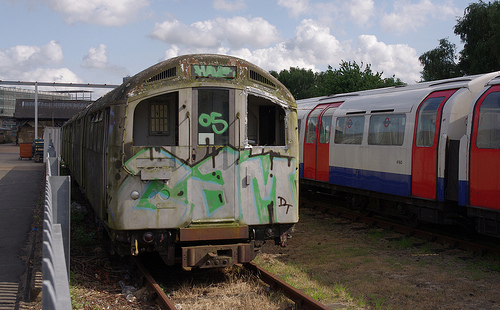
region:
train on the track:
[78, 48, 300, 274]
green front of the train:
[186, 99, 236, 144]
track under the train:
[153, 265, 294, 309]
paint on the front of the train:
[108, 64, 293, 242]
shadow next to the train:
[78, 258, 140, 308]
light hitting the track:
[223, 280, 273, 308]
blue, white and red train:
[343, 93, 475, 203]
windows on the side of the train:
[319, 103, 421, 159]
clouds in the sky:
[31, 11, 150, 71]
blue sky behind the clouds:
[6, 8, 32, 31]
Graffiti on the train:
[134, 150, 298, 216]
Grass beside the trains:
[298, 211, 498, 305]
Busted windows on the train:
[133, 97, 285, 144]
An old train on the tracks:
[61, 60, 294, 266]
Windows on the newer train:
[335, 108, 404, 146]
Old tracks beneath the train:
[145, 265, 325, 303]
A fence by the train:
[36, 137, 63, 308]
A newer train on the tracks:
[301, 72, 496, 227]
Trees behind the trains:
[285, 3, 492, 95]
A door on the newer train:
[308, 104, 330, 179]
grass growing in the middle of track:
[196, 275, 265, 297]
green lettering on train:
[193, 104, 237, 129]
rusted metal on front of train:
[173, 238, 267, 276]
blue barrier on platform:
[21, 191, 73, 297]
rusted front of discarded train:
[103, 49, 307, 244]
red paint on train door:
[416, 155, 431, 182]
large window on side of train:
[331, 108, 413, 150]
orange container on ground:
[7, 133, 41, 161]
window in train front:
[141, 98, 169, 138]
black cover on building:
[8, 90, 91, 120]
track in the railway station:
[122, 267, 303, 308]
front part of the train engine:
[116, 54, 311, 278]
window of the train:
[333, 109, 403, 150]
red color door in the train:
[407, 87, 476, 202]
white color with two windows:
[341, 93, 416, 198]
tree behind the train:
[288, 60, 415, 92]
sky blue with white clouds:
[157, 8, 419, 42]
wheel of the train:
[396, 204, 426, 229]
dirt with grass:
[297, 240, 472, 300]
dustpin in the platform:
[16, 140, 33, 162]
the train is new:
[325, 78, 499, 223]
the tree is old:
[103, 51, 283, 290]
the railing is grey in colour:
[38, 117, 67, 308]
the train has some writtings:
[190, 90, 230, 170]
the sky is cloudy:
[117, 8, 294, 50]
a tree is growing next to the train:
[304, 62, 361, 84]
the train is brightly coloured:
[318, 112, 381, 172]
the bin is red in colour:
[13, 141, 35, 160]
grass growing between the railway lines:
[293, 249, 355, 291]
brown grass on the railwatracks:
[189, 282, 254, 309]